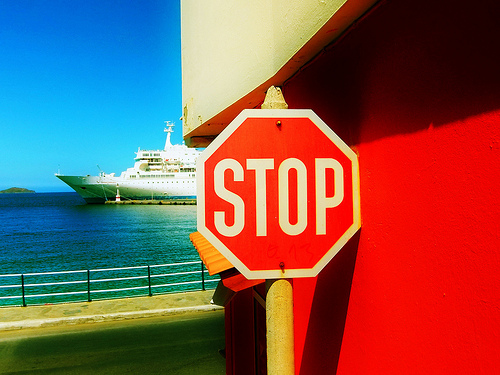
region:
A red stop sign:
[224, 123, 363, 271]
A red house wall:
[307, 295, 485, 373]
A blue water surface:
[125, 206, 185, 263]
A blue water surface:
[10, 233, 108, 290]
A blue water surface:
[32, 187, 94, 240]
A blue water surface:
[1, 198, 36, 240]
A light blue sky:
[13, 87, 86, 169]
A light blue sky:
[83, 18, 164, 145]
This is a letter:
[208, 150, 249, 248]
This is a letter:
[245, 151, 277, 251]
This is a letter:
[273, 152, 313, 246]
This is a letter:
[244, 152, 277, 244]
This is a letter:
[313, 153, 346, 243]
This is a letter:
[245, 153, 276, 240]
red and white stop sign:
[182, 105, 376, 290]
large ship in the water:
[45, 107, 199, 228]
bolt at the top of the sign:
[274, 118, 281, 130]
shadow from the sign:
[285, 232, 365, 373]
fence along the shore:
[1, 241, 217, 316]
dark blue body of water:
[0, 191, 223, 305]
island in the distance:
[1, 181, 41, 195]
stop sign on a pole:
[183, 73, 393, 373]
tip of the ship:
[48, 167, 63, 182]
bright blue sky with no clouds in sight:
[0, 0, 198, 193]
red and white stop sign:
[188, 98, 365, 293]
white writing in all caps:
[209, 146, 351, 243]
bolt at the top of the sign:
[273, 115, 285, 131]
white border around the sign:
[187, 108, 375, 288]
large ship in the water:
[48, 116, 198, 213]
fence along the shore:
[0, 249, 222, 309]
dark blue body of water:
[1, 187, 220, 309]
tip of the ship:
[52, 166, 62, 183]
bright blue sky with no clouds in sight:
[1, 0, 190, 191]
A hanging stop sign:
[196, 105, 390, 280]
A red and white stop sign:
[198, 92, 388, 293]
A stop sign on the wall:
[194, 109, 373, 286]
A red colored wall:
[353, 35, 498, 373]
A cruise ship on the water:
[46, 113, 198, 228]